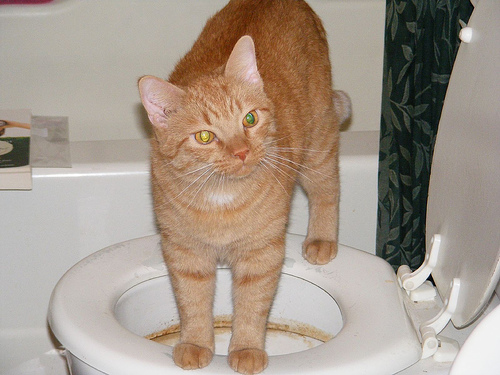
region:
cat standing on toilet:
[176, 8, 374, 372]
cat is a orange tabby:
[183, 18, 280, 266]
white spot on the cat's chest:
[204, 181, 245, 216]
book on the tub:
[0, 88, 88, 235]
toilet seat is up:
[421, 17, 479, 342]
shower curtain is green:
[385, 15, 432, 232]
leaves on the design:
[393, 45, 425, 169]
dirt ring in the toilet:
[104, 315, 395, 358]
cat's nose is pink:
[223, 136, 265, 171]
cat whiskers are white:
[151, 118, 356, 227]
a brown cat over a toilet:
[115, 2, 372, 369]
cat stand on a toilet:
[125, 0, 360, 371]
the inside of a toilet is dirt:
[127, 296, 342, 360]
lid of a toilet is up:
[412, 0, 499, 340]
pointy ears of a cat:
[116, 26, 276, 122]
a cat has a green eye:
[235, 106, 265, 133]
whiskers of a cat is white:
[170, 145, 320, 208]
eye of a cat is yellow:
[181, 123, 223, 146]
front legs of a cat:
[163, 243, 287, 373]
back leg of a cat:
[292, 140, 349, 272]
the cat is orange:
[120, 3, 382, 372]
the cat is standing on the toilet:
[38, 0, 495, 364]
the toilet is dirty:
[41, 191, 398, 370]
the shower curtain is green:
[368, 3, 498, 305]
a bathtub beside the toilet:
[1, 1, 480, 367]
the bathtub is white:
[2, 3, 494, 263]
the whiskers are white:
[152, 132, 344, 224]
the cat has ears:
[125, 34, 287, 129]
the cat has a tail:
[315, 66, 356, 143]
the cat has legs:
[141, 160, 362, 372]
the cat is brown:
[115, 28, 435, 354]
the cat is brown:
[93, 43, 290, 248]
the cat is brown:
[88, 70, 380, 364]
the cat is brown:
[127, 90, 309, 265]